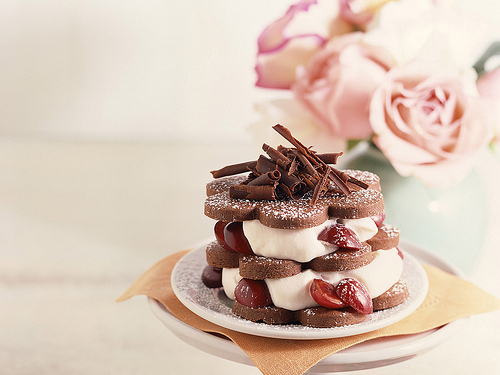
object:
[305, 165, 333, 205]
chocolate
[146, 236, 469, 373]
plate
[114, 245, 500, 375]
napkin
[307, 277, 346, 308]
strawberries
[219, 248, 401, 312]
cream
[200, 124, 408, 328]
cake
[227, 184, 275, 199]
chocolate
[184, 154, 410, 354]
desert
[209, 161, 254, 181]
chocolate shavings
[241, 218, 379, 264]
whipped cream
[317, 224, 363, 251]
cherry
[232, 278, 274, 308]
cherry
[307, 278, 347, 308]
cherry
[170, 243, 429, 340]
plate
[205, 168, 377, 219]
powdered sugar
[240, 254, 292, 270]
powdered sugar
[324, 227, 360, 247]
powdered sugar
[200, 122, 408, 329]
dessert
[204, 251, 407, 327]
layer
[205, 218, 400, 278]
layer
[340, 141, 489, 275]
vase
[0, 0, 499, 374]
table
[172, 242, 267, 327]
powdered sugar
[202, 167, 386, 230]
pastry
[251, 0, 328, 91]
edge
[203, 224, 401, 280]
cookie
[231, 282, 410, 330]
cookie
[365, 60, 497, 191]
rose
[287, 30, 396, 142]
rose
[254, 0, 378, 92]
rose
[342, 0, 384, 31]
rose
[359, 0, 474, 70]
rose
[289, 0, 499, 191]
flower bunch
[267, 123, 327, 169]
shaving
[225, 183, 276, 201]
shaving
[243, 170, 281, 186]
shaving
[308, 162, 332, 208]
shaving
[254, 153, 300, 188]
shaving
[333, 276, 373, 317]
cherry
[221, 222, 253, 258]
cherry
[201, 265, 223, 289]
cherry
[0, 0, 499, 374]
background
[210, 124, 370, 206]
pile